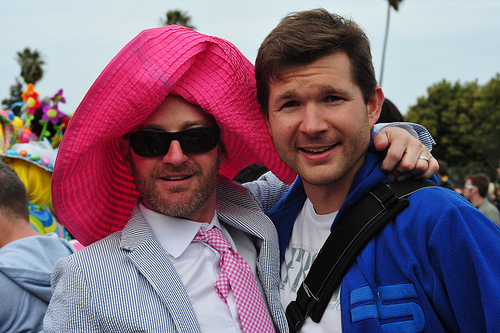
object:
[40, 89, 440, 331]
man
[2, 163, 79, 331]
man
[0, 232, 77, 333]
gray hoodie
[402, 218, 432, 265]
ground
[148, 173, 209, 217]
beard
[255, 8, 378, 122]
hair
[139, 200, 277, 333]
shirt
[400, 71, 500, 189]
trees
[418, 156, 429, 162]
ring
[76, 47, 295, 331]
man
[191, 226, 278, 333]
tie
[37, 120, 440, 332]
jacket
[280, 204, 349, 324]
shirt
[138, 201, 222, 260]
collar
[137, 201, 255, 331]
shirt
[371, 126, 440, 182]
finger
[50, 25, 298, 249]
hat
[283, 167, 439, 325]
black strap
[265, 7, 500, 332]
man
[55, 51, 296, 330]
man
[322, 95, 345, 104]
eye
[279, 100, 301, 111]
eye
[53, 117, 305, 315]
suit jacket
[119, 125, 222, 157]
sunglasses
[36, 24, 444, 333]
man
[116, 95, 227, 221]
head